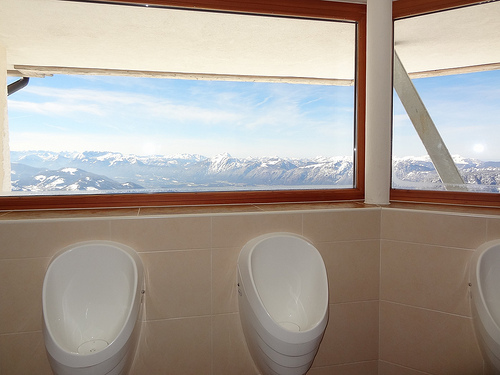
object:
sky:
[6, 75, 497, 165]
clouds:
[20, 77, 330, 135]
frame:
[2, 0, 364, 210]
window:
[11, 3, 361, 195]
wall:
[0, 208, 379, 373]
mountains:
[27, 165, 124, 193]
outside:
[3, 66, 498, 191]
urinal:
[40, 237, 140, 374]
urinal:
[240, 230, 328, 375]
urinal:
[468, 242, 500, 367]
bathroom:
[3, 2, 499, 375]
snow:
[12, 148, 478, 170]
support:
[7, 72, 28, 99]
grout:
[10, 204, 484, 373]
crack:
[205, 221, 216, 375]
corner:
[344, 0, 407, 207]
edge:
[0, 191, 355, 207]